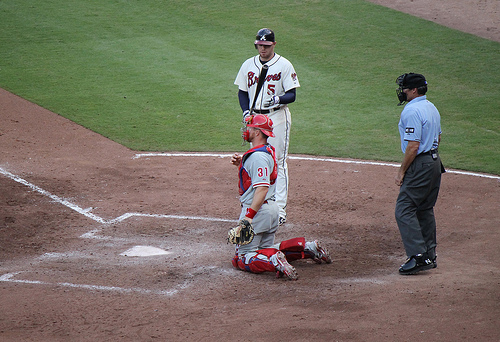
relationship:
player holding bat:
[188, 15, 333, 193] [249, 61, 311, 123]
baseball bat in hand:
[248, 64, 269, 114] [241, 107, 258, 122]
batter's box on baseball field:
[84, 200, 291, 297] [13, 3, 412, 321]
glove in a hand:
[223, 220, 257, 242] [226, 217, 258, 247]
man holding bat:
[234, 27, 301, 226] [250, 64, 270, 114]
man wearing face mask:
[395, 72, 447, 276] [395, 71, 428, 105]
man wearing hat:
[234, 27, 301, 226] [253, 26, 277, 46]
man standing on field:
[383, 54, 483, 276] [18, 12, 485, 327]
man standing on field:
[232, 25, 301, 227] [18, 12, 485, 327]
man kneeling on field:
[227, 109, 332, 278] [18, 12, 485, 327]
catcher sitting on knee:
[225, 115, 332, 282] [231, 249, 251, 272]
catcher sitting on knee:
[225, 115, 332, 282] [259, 243, 270, 249]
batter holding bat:
[234, 26, 295, 227] [252, 59, 264, 117]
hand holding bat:
[239, 109, 259, 119] [252, 59, 264, 117]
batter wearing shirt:
[234, 26, 295, 227] [234, 52, 297, 110]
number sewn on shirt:
[267, 80, 277, 99] [234, 52, 297, 110]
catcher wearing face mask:
[225, 115, 332, 282] [239, 112, 253, 148]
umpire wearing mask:
[394, 70, 446, 276] [394, 72, 429, 106]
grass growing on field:
[2, 6, 492, 169] [3, 4, 490, 340]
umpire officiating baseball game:
[394, 71, 446, 275] [2, 1, 484, 338]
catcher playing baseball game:
[223, 109, 333, 281] [2, 1, 484, 338]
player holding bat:
[234, 27, 301, 225] [243, 60, 268, 116]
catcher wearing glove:
[223, 109, 333, 281] [236, 218, 257, 243]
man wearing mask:
[227, 114, 332, 281] [239, 109, 256, 149]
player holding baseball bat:
[234, 27, 301, 225] [248, 64, 270, 114]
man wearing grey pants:
[227, 114, 332, 281] [225, 195, 306, 269]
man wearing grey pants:
[395, 72, 447, 276] [391, 144, 446, 265]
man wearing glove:
[227, 109, 332, 278] [226, 217, 256, 244]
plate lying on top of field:
[122, 236, 176, 260] [3, 4, 490, 340]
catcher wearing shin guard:
[225, 115, 332, 282] [211, 249, 276, 287]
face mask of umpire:
[395, 73, 427, 106] [385, 50, 463, 274]